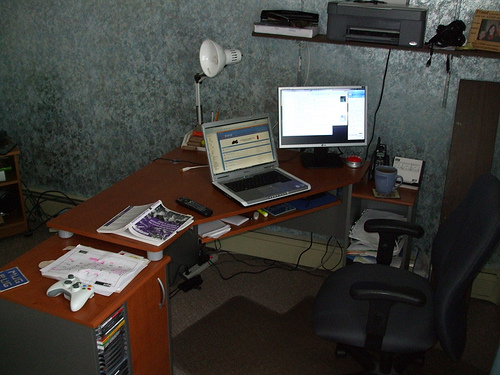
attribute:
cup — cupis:
[370, 165, 401, 198]